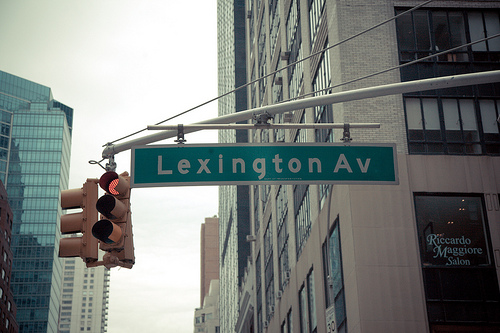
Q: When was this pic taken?
A: During the daytime.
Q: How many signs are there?
A: 1.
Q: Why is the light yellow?
A: Prepare to stop.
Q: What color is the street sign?
A: Green.